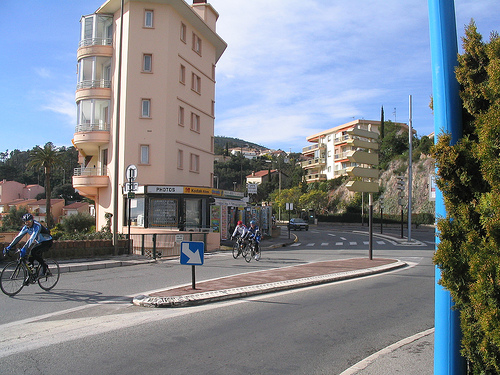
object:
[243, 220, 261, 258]
man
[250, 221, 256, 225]
helmet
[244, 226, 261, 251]
clothes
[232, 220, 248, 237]
person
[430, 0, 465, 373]
pole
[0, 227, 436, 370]
street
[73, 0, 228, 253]
building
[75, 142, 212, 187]
floor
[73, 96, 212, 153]
floor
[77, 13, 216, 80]
floor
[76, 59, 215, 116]
floor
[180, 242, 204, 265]
sign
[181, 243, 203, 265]
background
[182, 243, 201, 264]
arrow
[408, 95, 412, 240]
pole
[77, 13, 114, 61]
balcony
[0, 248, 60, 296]
bicycle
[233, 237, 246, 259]
bicycle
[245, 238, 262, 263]
bicycle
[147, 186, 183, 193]
sign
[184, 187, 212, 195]
sign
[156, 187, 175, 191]
lettering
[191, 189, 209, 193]
lettering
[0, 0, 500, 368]
photograph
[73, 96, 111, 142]
stories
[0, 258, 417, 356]
paint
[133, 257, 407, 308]
sidewalk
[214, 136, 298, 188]
mountain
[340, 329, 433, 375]
sidewalk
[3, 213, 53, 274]
man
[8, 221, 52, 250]
shirt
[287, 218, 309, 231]
car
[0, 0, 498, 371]
city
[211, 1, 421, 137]
clouds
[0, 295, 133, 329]
lines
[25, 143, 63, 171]
leaves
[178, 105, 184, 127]
window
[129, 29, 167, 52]
wall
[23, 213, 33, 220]
helmet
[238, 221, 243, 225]
helmet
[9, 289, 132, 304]
shadow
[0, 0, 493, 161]
sky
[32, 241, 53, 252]
black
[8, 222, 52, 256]
blue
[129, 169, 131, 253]
post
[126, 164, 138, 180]
sign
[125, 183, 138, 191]
sign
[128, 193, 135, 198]
sign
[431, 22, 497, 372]
tree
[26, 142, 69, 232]
tree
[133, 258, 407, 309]
median